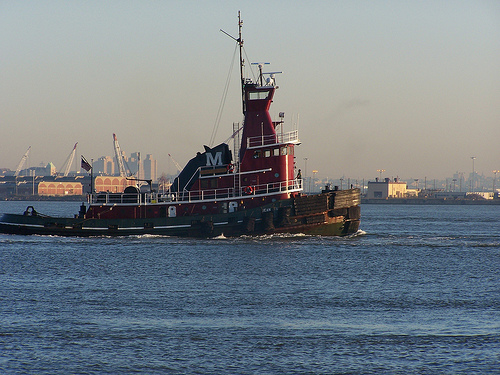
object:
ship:
[3, 9, 369, 237]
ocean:
[1, 196, 495, 374]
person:
[295, 161, 303, 181]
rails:
[90, 177, 304, 205]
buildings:
[82, 136, 165, 183]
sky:
[8, 1, 492, 164]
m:
[206, 152, 225, 166]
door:
[168, 207, 176, 217]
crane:
[111, 132, 128, 180]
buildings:
[21, 176, 128, 195]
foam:
[131, 233, 228, 241]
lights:
[309, 168, 326, 177]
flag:
[78, 154, 92, 177]